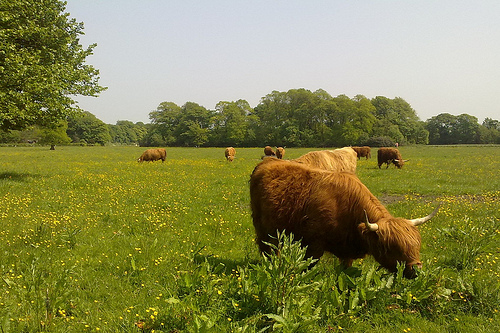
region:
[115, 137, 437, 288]
a herd of cattle in a pasture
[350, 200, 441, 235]
the cow has horns on the head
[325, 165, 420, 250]
the fur is long on the cow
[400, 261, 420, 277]
the cow has a black nose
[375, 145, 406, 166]
a cow in the background has horns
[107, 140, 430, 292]
the cows are grazing in a field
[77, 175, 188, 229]
yellow flowers are blooming in the field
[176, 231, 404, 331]
weeds are growing in the field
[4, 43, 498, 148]
tress are around the field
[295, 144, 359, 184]
a light colored cow is in the field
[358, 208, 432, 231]
Horns on a cow's head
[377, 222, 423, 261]
Brown hair covering a cow's face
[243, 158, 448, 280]
Brown cow grazing in a field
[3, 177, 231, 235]
yellow flowers in a field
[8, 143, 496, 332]
Green grass in a field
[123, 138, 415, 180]
Cows eating grass in a field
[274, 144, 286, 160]
Cow with it's head up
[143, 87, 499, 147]
Trees behind cows in a field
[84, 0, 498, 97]
Grey sky above a field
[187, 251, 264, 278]
Cow's shadow in the grass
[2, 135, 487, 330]
the grass on the ground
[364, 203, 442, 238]
the horns on the animal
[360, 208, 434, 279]
the animal's head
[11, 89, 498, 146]
the trees in the distance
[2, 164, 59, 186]
the shadow near the tree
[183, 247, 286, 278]
the shadow on the ground near the brown animal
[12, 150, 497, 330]
the small yellow flowers on the grass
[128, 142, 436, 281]
the group of animals on the grass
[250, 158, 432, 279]
the brown hair on the animal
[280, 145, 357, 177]
the light colored animal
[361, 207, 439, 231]
a pair of white horns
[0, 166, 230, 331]
a field of yellow flowers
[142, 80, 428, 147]
a lot of green leaf trees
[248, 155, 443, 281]
a brown shaggy cow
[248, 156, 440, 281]
a brown cow eating grass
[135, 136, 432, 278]
a bunch of cows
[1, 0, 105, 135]
a bunch of green leafs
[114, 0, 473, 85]
a patch of blue sky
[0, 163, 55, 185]
a shadow of a tree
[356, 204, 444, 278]
a head of a cow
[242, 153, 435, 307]
a long hair cow grazing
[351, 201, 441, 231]
a set of horns on a cow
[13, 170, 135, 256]
flowers growing in a field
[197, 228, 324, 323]
green weeds in a feed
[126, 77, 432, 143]
a group of trees in the field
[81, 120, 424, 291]
a herd of cattle grazing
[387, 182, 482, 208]
gray dirt in a field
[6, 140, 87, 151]
a line of bushes in the field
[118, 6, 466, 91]
clear skys over the field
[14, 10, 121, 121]
green leaves on a tree